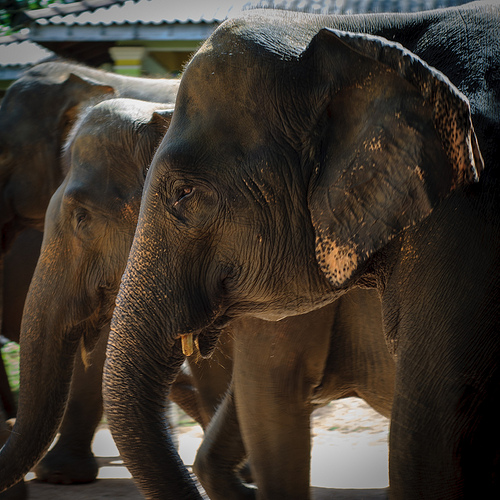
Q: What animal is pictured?
A: Elephant.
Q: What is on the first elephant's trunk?
A: Dirt.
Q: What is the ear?
A: Of the elephant.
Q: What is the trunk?
A: Of the elephant.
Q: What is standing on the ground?
A: Group of grey elephants.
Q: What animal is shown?
A: Elephant.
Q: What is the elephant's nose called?
A: Trunk.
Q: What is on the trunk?
A: Coils.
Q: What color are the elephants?
A: Gray.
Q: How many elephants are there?
A: Three.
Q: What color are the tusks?
A: White.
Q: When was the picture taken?
A: Daytime.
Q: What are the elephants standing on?
A: Dirt.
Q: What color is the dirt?
A: Brown.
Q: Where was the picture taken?
A: At a zoo.